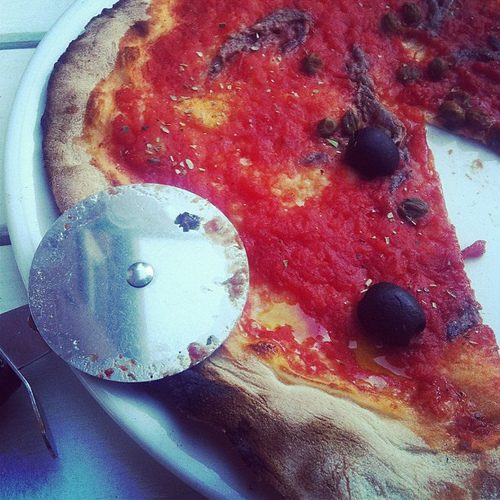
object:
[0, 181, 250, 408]
cutter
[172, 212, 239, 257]
grime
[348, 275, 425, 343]
olive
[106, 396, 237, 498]
plate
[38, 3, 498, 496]
food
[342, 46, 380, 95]
marks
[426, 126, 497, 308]
empty spot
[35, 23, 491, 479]
pita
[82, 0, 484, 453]
cheese topping